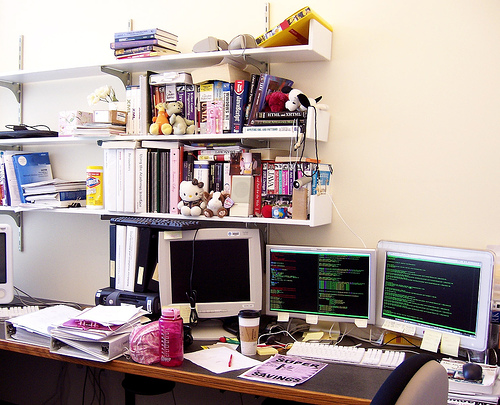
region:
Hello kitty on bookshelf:
[99, 144, 336, 235]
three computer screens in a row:
[136, 213, 483, 350]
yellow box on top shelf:
[230, 9, 338, 54]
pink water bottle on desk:
[112, 292, 191, 378]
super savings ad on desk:
[236, 338, 325, 398]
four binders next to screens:
[86, 220, 153, 292]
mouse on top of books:
[448, 355, 488, 400]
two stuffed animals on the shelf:
[143, 100, 193, 140]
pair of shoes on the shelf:
[14, 114, 47, 139]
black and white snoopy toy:
[274, 77, 328, 122]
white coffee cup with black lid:
[236, 308, 260, 355]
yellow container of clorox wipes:
[86, 162, 102, 208]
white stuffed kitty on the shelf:
[176, 178, 204, 216]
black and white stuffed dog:
[283, 83, 323, 110]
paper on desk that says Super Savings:
[238, 351, 328, 387]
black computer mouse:
[461, 361, 481, 381]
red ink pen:
[227, 352, 234, 367]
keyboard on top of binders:
[109, 214, 197, 229]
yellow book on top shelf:
[255, 6, 334, 48]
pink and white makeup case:
[127, 318, 163, 364]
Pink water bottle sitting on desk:
[155, 305, 183, 366]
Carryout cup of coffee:
[231, 307, 261, 357]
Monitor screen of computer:
[167, 240, 248, 302]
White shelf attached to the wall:
[0, 16, 335, 227]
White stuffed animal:
[175, 177, 205, 215]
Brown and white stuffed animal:
[202, 186, 228, 216]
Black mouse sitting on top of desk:
[461, 357, 481, 383]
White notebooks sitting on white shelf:
[101, 141, 147, 213]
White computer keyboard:
[283, 333, 409, 369]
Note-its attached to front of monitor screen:
[414, 326, 462, 361]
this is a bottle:
[161, 300, 181, 366]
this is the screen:
[388, 243, 470, 337]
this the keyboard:
[311, 342, 360, 358]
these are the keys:
[313, 345, 342, 356]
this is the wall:
[365, 20, 477, 192]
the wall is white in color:
[341, 61, 426, 140]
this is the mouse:
[463, 357, 483, 379]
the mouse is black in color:
[461, 365, 478, 373]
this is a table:
[316, 374, 343, 385]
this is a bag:
[137, 323, 160, 357]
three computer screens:
[152, 224, 496, 382]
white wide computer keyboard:
[264, 331, 423, 377]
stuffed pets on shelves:
[98, 94, 286, 219]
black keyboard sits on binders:
[107, 207, 209, 250]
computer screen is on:
[261, 236, 382, 333]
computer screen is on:
[372, 229, 497, 357]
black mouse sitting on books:
[412, 346, 492, 402]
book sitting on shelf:
[78, 68, 331, 148]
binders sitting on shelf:
[85, 138, 331, 229]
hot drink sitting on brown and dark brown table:
[231, 303, 266, 360]